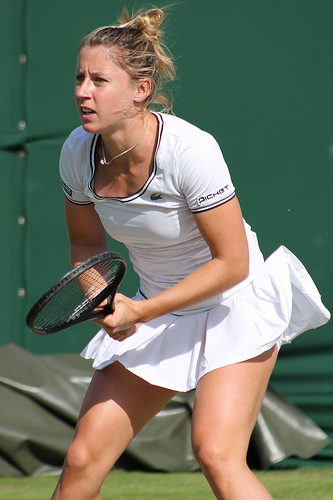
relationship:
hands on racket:
[92, 294, 138, 338] [26, 251, 114, 323]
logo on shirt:
[146, 190, 167, 205] [57, 113, 264, 306]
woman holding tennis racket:
[26, 9, 331, 498] [23, 248, 141, 344]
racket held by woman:
[24, 249, 122, 336] [26, 9, 331, 498]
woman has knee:
[26, 9, 331, 498] [62, 439, 94, 469]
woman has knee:
[26, 9, 331, 498] [193, 442, 229, 472]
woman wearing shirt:
[26, 9, 331, 498] [55, 108, 268, 319]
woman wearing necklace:
[26, 9, 331, 498] [92, 111, 151, 167]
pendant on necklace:
[98, 156, 107, 165] [92, 111, 151, 167]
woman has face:
[26, 9, 331, 498] [73, 43, 132, 136]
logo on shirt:
[146, 190, 167, 205] [55, 108, 268, 319]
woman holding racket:
[26, 9, 331, 498] [24, 249, 122, 336]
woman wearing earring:
[26, 9, 331, 498] [133, 96, 145, 101]